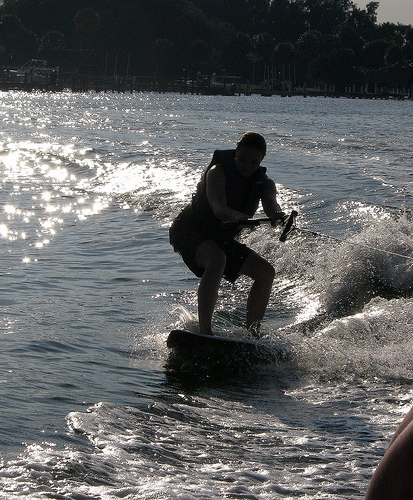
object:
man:
[168, 127, 290, 339]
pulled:
[272, 197, 359, 259]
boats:
[0, 55, 401, 97]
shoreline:
[2, 3, 412, 68]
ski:
[279, 201, 412, 289]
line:
[280, 210, 412, 260]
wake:
[246, 194, 410, 418]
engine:
[366, 207, 411, 397]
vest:
[190, 150, 283, 228]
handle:
[279, 209, 299, 243]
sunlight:
[0, 87, 204, 259]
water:
[0, 88, 412, 499]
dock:
[0, 53, 393, 98]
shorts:
[169, 206, 261, 278]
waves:
[0, 131, 207, 247]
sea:
[0, 95, 412, 498]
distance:
[47, 12, 390, 52]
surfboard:
[166, 325, 273, 357]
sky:
[324, 0, 412, 26]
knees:
[201, 252, 278, 280]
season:
[0, 7, 412, 496]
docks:
[0, 67, 412, 98]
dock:
[0, 73, 411, 100]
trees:
[0, 1, 412, 83]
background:
[0, 0, 412, 191]